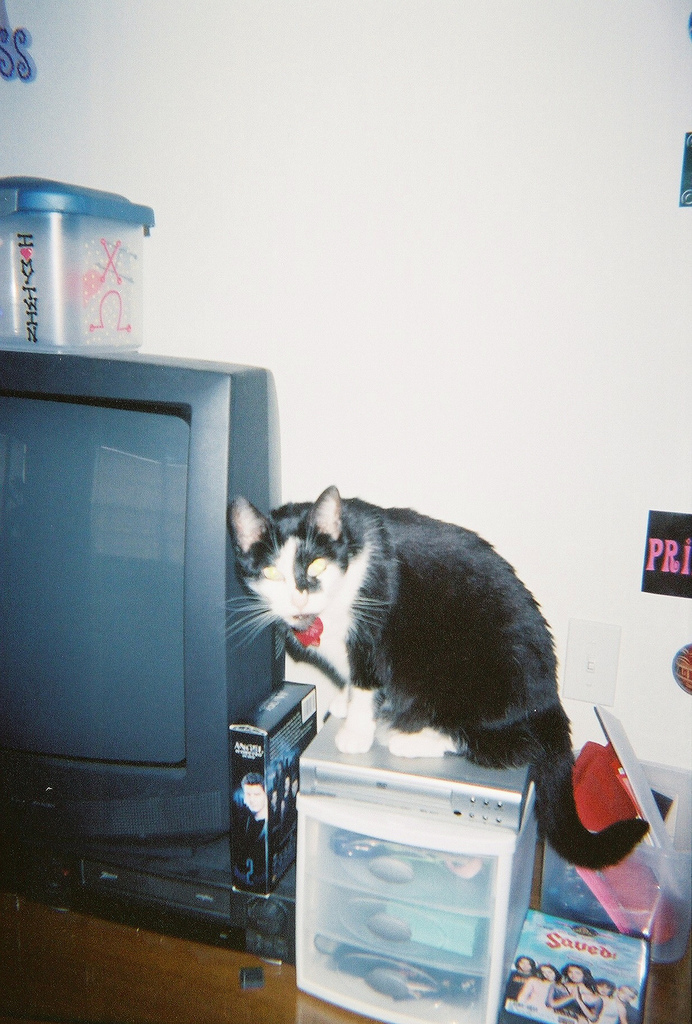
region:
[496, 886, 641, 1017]
A DVD.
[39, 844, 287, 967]
A black VCR.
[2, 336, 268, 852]
A television on top of a VCR.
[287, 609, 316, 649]
A cat ID tag.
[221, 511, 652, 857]
A black and white cat.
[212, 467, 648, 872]
A cat on top of a DVD player.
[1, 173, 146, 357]
A container with a blue lid.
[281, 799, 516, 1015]
White and clear small drawers.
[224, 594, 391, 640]
White whiskers on a cat.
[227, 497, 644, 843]
a cat sitting on a DVD player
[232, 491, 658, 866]
a black and white cat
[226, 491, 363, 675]
a cat with a red tag on its neck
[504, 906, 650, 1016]
the case of a DVD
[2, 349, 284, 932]
a television sitting on a VCR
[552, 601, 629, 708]
a white jack on the wall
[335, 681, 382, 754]
the white paw of an animal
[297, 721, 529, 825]
a silver DVD player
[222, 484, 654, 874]
black cat with white face and chest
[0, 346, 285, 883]
old fashion tube television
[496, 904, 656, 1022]
dvd cover displaying five people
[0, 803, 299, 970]
black colored vhs player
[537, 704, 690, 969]
transparent storage container with open lid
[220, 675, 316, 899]
vhs cassette tape in original box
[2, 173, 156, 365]
plastic storage container with lid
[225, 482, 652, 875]
domestic cat with red collar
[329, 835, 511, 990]
a view of shelves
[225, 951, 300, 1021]
a dust in floor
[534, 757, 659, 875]
tail of the cat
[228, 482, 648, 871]
a black cat with a white patch on it's chest and paws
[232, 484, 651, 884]
a black cat with a red charm on it's collar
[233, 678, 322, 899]
a Angel season 2 DVD set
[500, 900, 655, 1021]
a Saved movie DVD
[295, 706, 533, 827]
a silver DVD player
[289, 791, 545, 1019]
a white storage bin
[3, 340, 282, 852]
a black tube television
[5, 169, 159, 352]
a plastic bin with a blue top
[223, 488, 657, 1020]
animal on a box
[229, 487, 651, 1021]
black and white cat on a box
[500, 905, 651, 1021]
DVD on the floor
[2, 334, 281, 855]
large black television against a wall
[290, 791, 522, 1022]
white plastic drawers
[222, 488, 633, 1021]
cat crouched on top of a silver box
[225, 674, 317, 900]
a black boxed DVD set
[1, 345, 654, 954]
cat next to a black television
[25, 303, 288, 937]
tv on the side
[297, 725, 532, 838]
a gray dvd player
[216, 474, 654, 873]
a black and white cat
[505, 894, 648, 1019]
dvd next to container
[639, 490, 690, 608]
a black and pink sign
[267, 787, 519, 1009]
a clear plastic container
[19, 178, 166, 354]
a bin on top of tv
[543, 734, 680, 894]
tail of the cat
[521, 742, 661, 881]
the tail is curved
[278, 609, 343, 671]
collar on the cat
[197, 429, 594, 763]
a white and black cat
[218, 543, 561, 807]
a cat on a dvd player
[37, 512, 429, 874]
a cat next to a t.v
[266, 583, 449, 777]
a cat with white on its foot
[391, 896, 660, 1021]
a dvd next to a box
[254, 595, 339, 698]
a red tag on a cats neck